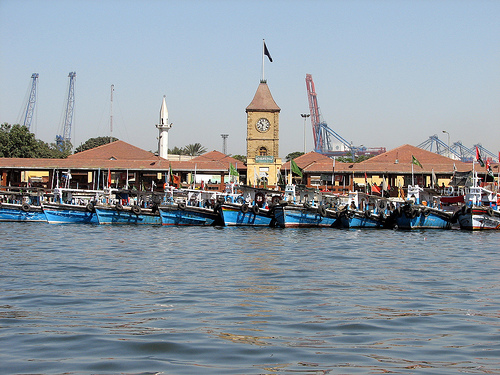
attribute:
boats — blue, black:
[2, 178, 492, 228]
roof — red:
[260, 117, 472, 185]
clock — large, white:
[252, 112, 273, 136]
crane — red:
[292, 67, 363, 166]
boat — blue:
[0, 190, 43, 222]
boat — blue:
[39, 189, 92, 222]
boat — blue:
[93, 187, 160, 220]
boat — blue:
[157, 191, 217, 222]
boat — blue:
[215, 192, 274, 227]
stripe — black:
[0, 204, 42, 214]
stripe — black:
[43, 210, 91, 219]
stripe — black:
[98, 212, 143, 222]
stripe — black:
[161, 213, 207, 224]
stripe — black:
[283, 211, 322, 222]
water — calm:
[0, 220, 498, 372]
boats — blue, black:
[145, 186, 314, 236]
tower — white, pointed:
[154, 84, 186, 170]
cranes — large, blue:
[50, 59, 102, 160]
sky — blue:
[52, 16, 184, 71]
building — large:
[230, 56, 323, 179]